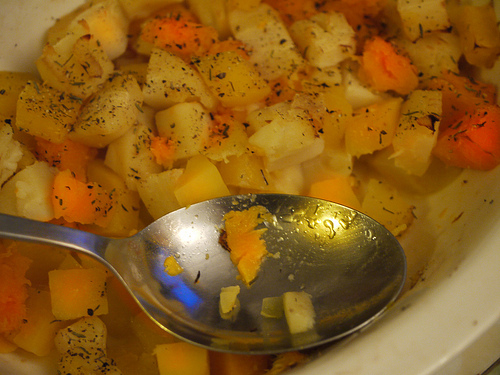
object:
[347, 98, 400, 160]
potatoe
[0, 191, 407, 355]
spoon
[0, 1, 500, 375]
bowl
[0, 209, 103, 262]
handle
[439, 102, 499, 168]
carrot